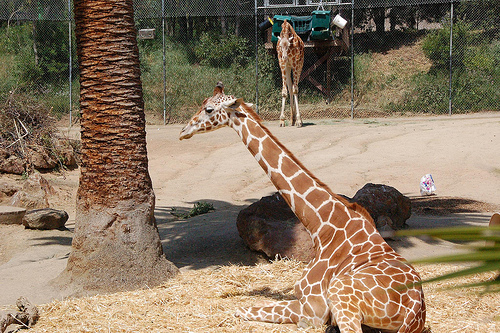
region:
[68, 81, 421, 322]
giraffe next to a tree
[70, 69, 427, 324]
healthy giraffe next to a tree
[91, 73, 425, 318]
tired giraffe next to a tree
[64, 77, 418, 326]
relaxing giraffe next to a tree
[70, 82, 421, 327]
tall giraffe next to a tree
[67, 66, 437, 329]
big giraffe next to a tree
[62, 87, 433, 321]
attractive giraffe next to a tree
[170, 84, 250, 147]
head of a giraffe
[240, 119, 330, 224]
neck of a giraffe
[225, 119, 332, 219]
long neck of a giraffe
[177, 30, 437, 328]
two girrafes in a zoo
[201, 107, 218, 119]
the closest giraffes eye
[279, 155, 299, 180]
brown spot on giraffe neck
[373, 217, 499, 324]
green on bottom right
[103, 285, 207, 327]
hay on the ground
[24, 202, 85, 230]
a rock behind the tree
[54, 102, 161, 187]
a brown tree trunk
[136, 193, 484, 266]
a shadow of a tree on ground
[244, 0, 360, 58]
something blue behind the giraffe in back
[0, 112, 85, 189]
a pile of brush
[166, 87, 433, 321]
the giraffe is laying down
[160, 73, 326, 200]
giraffe is looking left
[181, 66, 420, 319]
giraffe is sitting under tree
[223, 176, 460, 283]
rocks are behind giraffe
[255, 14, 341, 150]
giraffe is facing towards camera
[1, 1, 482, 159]
metal fence containing giraffes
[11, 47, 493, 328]
giraffe is laying on straw grass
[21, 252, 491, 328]
the straw grass is yellow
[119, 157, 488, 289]
shadow of tree on ground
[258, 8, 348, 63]
green object behind giraffe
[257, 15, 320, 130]
A giraffe is standing in the background.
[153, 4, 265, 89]
A fence is behind the giraffe.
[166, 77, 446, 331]
One giraffe is sitting down.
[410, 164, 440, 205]
A paper bag.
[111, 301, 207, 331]
The grass is brown.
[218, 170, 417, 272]
Rocks are behind the giraffe.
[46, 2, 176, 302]
A large tree trunk.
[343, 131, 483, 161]
The ground is dirt.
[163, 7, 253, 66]
Trees are in the background.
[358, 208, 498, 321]
A fe leaves are showing the the right.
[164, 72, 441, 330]
giraffe laying down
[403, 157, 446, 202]
a white bag on the dirt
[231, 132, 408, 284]
the giraffe has brown spots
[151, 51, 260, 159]
giraffe looking to the left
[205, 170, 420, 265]
2 big boulder rocks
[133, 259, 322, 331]
giraffe laying on the hay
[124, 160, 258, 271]
shadow of a tree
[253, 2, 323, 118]
a giraffe walking slow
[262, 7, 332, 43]
the feeder for the animals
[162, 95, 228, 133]
giraffe eye is open